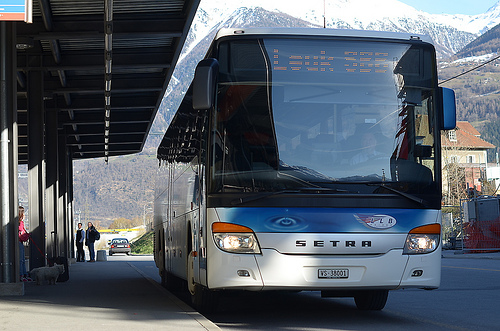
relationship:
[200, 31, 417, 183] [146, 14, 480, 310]
windshield of bus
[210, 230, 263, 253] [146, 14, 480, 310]
headlight on front of bus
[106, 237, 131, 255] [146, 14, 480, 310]
car driving behind bus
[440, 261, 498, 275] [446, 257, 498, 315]
paint on road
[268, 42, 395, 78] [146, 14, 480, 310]
sing on bus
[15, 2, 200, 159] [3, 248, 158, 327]
roof over platform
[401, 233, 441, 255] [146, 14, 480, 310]
headlight on front of bus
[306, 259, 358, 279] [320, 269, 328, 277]
tag has letters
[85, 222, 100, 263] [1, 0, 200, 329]
people in front of building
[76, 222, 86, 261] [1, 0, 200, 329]
people in front of building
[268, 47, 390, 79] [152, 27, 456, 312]
letters on top of bus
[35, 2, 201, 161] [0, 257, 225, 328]
awning over sidewalk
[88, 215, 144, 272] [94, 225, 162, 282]
car on street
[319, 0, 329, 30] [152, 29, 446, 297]
antenna on bus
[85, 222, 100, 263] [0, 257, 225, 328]
people on sidewalk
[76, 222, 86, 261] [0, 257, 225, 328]
people on sidewalk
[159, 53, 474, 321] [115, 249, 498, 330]
bus parked at road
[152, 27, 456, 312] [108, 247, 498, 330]
bus parked at street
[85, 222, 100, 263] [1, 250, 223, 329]
people standing on a sidewalk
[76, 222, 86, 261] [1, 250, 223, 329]
people standing on a sidewalk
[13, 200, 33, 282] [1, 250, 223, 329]
person standing on a sidewalk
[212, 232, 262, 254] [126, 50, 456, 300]
headlight on bus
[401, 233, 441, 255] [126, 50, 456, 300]
headlight on bus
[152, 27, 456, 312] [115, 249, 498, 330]
bus on road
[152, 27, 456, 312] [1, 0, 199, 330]
bus parked at bus terminal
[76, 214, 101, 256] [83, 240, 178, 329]
people standing at sidewalk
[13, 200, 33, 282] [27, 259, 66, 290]
person walking a dog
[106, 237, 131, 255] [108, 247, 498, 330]
car riding street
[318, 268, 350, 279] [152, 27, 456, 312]
tag in front of bus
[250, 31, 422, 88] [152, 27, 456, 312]
sign in front of bus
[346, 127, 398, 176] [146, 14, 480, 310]
driver of bus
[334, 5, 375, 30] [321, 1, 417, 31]
snow on top of mountains